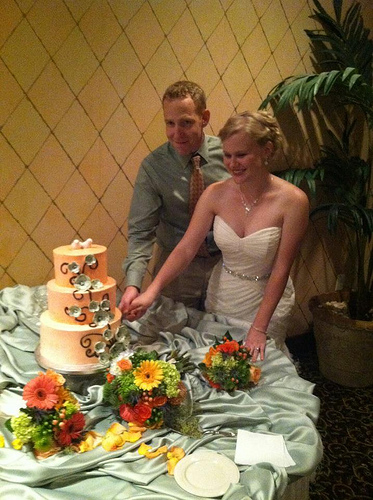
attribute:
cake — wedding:
[35, 231, 126, 377]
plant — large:
[259, 0, 371, 313]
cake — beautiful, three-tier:
[39, 236, 131, 374]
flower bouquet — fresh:
[4, 366, 93, 459]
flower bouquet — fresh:
[102, 348, 196, 444]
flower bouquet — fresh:
[198, 332, 262, 401]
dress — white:
[180, 106, 311, 371]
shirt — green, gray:
[120, 134, 233, 287]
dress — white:
[206, 212, 294, 350]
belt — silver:
[217, 257, 271, 288]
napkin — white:
[229, 417, 296, 478]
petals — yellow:
[84, 417, 186, 495]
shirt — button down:
[117, 132, 244, 295]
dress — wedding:
[183, 219, 281, 345]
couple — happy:
[116, 79, 308, 364]